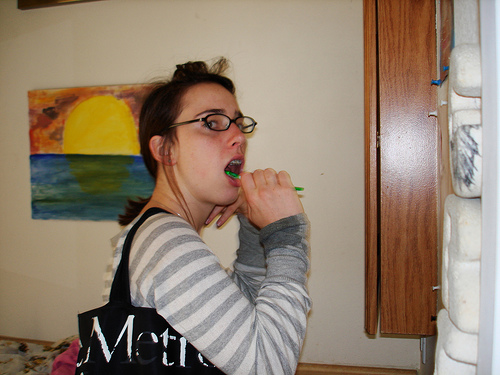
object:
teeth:
[230, 159, 241, 166]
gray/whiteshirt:
[102, 211, 313, 373]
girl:
[76, 58, 312, 374]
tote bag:
[74, 208, 236, 374]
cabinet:
[361, 0, 455, 339]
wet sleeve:
[259, 214, 301, 250]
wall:
[0, 0, 428, 375]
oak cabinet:
[360, 0, 452, 338]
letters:
[75, 316, 212, 368]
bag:
[76, 207, 223, 375]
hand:
[203, 167, 303, 232]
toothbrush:
[224, 171, 304, 192]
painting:
[25, 80, 167, 221]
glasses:
[159, 113, 254, 134]